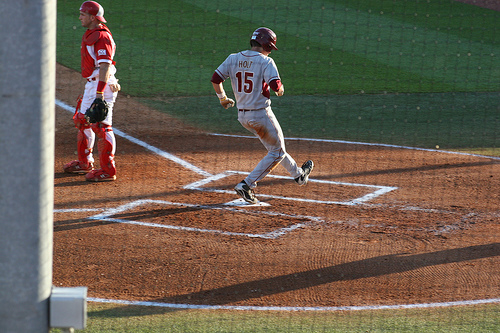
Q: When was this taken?
A: During the day.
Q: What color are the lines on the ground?
A: White.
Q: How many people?
A: Two.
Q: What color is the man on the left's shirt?
A: Red.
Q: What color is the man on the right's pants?
A: Gray.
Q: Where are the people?
A: In a field.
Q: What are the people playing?
A: Baseball.